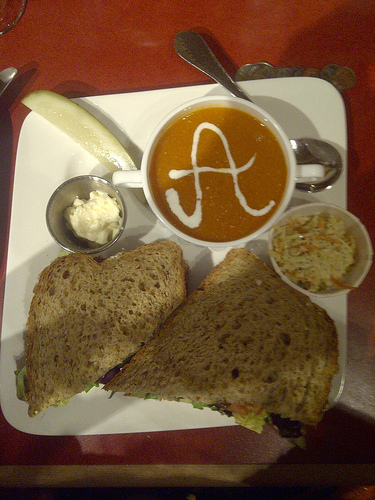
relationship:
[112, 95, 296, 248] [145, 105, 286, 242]
bowl of soup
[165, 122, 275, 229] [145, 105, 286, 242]
letter on soup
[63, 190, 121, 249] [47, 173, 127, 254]
butter in container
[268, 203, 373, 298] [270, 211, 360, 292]
bowl of cole slaw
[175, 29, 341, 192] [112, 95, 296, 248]
silver spoon behind bowl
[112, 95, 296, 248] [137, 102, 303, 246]
bowl of soup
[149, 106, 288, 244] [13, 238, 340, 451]
orange soup and sandwich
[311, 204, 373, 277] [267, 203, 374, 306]
bowl of relish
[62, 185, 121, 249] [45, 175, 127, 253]
butter in container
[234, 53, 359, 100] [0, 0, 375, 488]
coins on table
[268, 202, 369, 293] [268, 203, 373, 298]
coleslaw in bowl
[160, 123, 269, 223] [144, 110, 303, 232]
letter in soup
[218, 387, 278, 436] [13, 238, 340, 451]
lettuce inside sandwich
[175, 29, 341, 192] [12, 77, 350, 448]
silver spoon on plate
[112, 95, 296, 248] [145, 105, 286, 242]
bowl with soup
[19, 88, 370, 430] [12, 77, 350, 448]
food on plate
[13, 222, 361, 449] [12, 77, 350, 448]
sandwich on plate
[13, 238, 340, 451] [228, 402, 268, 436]
sandwich has lettuce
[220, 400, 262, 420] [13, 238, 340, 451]
tomatoes are in sandwich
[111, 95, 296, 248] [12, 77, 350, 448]
bowl on plate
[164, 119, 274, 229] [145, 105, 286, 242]
sauce on soup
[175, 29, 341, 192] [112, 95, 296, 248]
silver spoon next to bowl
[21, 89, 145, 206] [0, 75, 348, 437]
pickle on dinner plate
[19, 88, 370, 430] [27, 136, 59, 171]
food on dinner plate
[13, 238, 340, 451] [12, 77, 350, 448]
sandwich on plate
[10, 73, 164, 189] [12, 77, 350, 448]
pickle on plate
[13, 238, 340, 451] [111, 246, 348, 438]
sandwich has bread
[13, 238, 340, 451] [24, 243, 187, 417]
sandwich has bread